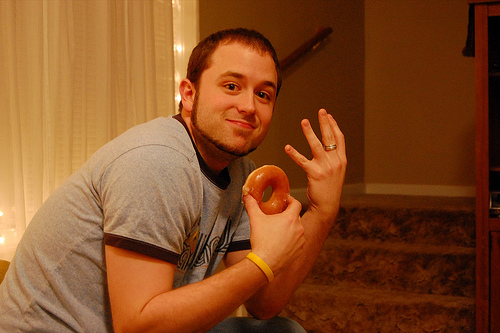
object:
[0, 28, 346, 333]
man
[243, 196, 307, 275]
hand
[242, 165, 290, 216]
donut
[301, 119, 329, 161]
fingers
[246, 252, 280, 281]
wrist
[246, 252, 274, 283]
band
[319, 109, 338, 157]
finger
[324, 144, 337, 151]
ring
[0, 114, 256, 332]
shirt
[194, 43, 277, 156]
face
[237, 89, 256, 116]
nose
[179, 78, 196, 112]
ear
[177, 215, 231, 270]
writing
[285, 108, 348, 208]
hand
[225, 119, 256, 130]
mouth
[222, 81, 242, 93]
eye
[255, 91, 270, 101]
eye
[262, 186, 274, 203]
hole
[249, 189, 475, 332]
staircase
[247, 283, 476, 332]
stair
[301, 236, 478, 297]
stair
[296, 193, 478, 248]
stair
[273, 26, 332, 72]
railing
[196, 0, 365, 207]
wall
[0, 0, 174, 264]
curtain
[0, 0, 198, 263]
window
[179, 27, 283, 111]
hair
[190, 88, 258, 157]
beard